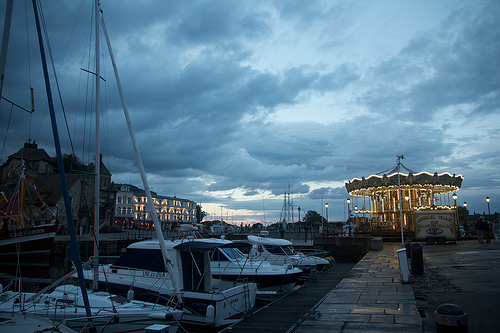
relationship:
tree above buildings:
[299, 209, 329, 240] [0, 139, 197, 228]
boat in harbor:
[72, 235, 259, 329] [1, 187, 285, 314]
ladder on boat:
[239, 274, 254, 314] [71, 233, 258, 324]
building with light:
[102, 185, 202, 233] [179, 204, 189, 215]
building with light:
[102, 185, 202, 233] [172, 205, 182, 213]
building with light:
[102, 185, 202, 233] [165, 205, 176, 215]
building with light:
[102, 185, 202, 233] [159, 195, 171, 207]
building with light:
[102, 185, 202, 233] [134, 203, 146, 213]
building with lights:
[341, 148, 474, 241] [387, 162, 445, 184]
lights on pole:
[321, 195, 353, 207] [347, 203, 349, 226]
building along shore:
[102, 185, 202, 233] [7, 139, 487, 282]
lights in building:
[110, 189, 201, 224] [116, 187, 196, 228]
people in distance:
[444, 209, 499, 247] [401, 205, 499, 248]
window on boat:
[119, 246, 167, 271] [76, 231, 300, 299]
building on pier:
[341, 148, 467, 244] [277, 236, 424, 328]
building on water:
[102, 185, 209, 232] [9, 260, 79, 280]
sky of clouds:
[1, 2, 499, 232] [119, 54, 283, 176]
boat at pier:
[195, 221, 289, 283] [19, 228, 497, 331]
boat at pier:
[72, 235, 259, 329] [1, 214, 430, 330]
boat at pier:
[64, 222, 249, 332] [220, 228, 487, 330]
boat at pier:
[0, 281, 181, 333] [313, 172, 437, 322]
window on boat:
[262, 236, 312, 263] [242, 222, 329, 277]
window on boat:
[208, 247, 243, 262] [173, 237, 303, 288]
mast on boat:
[3, 0, 186, 331] [58, 237, 255, 327]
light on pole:
[324, 200, 328, 209] [321, 201, 333, 226]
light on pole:
[486, 197, 491, 203] [348, 202, 349, 231]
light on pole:
[448, 192, 460, 200] [448, 186, 458, 209]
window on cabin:
[208, 247, 243, 262] [183, 238, 249, 273]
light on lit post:
[483, 195, 492, 204] [487, 203, 492, 228]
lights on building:
[136, 196, 183, 218] [106, 184, 213, 229]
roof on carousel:
[345, 155, 462, 195] [342, 152, 463, 239]